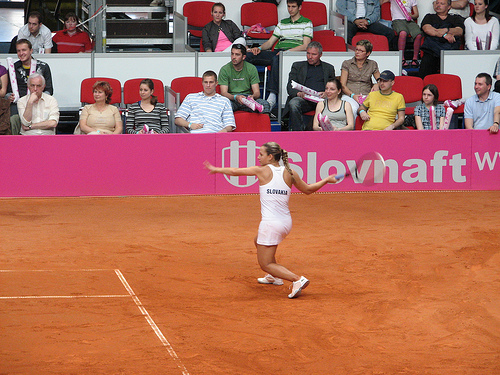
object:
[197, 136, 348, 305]
woman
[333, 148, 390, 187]
racket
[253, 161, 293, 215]
top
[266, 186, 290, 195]
slovakia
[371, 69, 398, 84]
hat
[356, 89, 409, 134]
shirt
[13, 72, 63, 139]
man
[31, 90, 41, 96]
lip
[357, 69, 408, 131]
man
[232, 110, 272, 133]
seat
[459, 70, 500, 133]
man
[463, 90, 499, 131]
blue polo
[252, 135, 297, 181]
hair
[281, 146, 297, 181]
ponytail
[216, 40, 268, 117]
man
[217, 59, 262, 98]
green shirt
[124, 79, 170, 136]
spectators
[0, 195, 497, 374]
court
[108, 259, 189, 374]
line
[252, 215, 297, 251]
white shorts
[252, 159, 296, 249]
dress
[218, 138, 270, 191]
logo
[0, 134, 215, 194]
tennis wall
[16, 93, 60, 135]
shirt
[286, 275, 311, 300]
white shoes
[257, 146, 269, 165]
side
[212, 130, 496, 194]
sign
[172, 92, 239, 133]
shirt